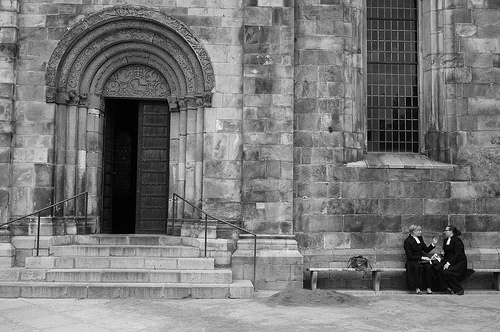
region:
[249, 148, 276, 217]
the wall is white in colour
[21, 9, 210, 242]
the door step is dome shaped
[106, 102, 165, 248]
the door is brown in colour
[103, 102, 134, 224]
the door is open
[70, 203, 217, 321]
there are stairs at the doorstep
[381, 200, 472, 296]
two people are seated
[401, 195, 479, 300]
they are wearing black costumes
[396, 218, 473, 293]
the ladies are talking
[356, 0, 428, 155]
the window has glasses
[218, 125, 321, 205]
the door is bricked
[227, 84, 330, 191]
STONE BRICKS ON BUILDING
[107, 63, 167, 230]
OPEN DOOR ATOP STEPS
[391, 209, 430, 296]
WOMAN SITTING ON SIDE OF BUILDING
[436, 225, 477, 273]
WOMAN SITTING ON SIDE OF BUILDING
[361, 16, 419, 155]
GLASS WINDOW ON BUILDING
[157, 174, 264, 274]
METAL RAIL ALONG STAIRS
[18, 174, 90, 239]
METAL RAIL ALONG STAIRS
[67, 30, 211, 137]
STONE ARCHWAY OVER DOOR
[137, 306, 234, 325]
CONCRETE ROAD IN FOREGROUND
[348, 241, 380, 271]
SMALL BIRD BY BUILDING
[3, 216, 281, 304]
large stone steps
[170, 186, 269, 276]
black railing on steps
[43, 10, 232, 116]
large curved arch way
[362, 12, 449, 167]
iron bars across window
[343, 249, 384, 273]
black purse on bench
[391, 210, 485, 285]
women sitting on bench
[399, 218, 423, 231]
short blond hair cut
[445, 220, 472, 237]
black hair in ponytail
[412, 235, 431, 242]
white collar around neck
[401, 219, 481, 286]
women wearing long black dress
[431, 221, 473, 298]
This is a person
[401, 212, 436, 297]
This is a person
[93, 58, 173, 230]
This is a door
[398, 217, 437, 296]
a person sitting on a bench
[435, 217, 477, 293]
a woman sitting on a bench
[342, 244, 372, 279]
a bag on a bench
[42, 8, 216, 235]
an arched doorway on the building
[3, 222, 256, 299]
stairs up to the door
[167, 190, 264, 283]
a rail by the stairway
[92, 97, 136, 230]
the left door is open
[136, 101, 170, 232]
the right door is closed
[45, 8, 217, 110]
the archway is carved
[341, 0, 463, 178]
a window in the building